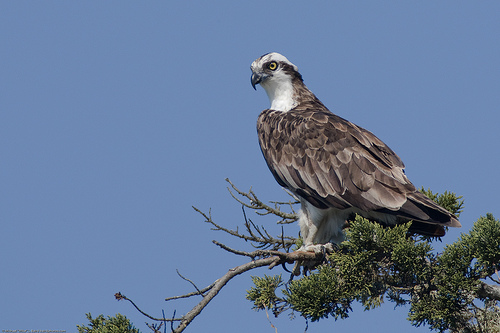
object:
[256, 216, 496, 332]
needles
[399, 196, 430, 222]
feathers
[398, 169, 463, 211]
leaves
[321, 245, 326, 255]
claw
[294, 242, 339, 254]
foot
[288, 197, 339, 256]
leg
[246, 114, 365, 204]
grey breast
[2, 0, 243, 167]
sky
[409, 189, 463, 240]
tail feathers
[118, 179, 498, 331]
branch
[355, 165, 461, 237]
tail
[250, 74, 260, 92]
beak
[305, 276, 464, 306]
leaves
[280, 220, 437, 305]
green leaves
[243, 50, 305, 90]
head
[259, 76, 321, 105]
neck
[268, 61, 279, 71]
eye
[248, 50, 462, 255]
bird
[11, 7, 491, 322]
clear blue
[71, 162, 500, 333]
tree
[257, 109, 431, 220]
wing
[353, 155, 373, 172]
feather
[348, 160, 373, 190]
feather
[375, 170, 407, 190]
feather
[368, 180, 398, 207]
feather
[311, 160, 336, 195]
feather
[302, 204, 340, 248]
legs